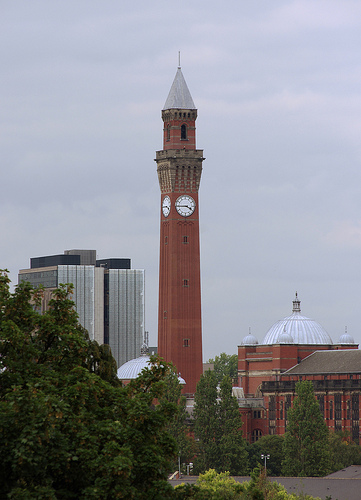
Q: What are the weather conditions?
A: It is cloudy.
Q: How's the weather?
A: It is cloudy.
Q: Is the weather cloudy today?
A: Yes, it is cloudy.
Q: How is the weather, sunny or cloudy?
A: It is cloudy.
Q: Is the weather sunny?
A: No, it is cloudy.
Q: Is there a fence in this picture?
A: No, there are no fences.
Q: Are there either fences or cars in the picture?
A: No, there are no fences or cars.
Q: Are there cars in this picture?
A: No, there are no cars.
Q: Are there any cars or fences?
A: No, there are no cars or fences.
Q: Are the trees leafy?
A: Yes, the trees are leafy.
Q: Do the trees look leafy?
A: Yes, the trees are leafy.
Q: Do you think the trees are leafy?
A: Yes, the trees are leafy.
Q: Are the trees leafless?
A: No, the trees are leafy.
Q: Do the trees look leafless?
A: No, the trees are leafy.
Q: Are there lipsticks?
A: No, there are no lipsticks.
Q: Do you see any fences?
A: No, there are no fences.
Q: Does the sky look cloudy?
A: Yes, the sky is cloudy.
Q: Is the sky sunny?
A: No, the sky is cloudy.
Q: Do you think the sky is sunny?
A: No, the sky is cloudy.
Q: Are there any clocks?
A: Yes, there is a clock.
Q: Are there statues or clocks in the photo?
A: Yes, there is a clock.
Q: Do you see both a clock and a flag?
A: No, there is a clock but no flags.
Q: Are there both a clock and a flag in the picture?
A: No, there is a clock but no flags.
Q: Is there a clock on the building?
A: Yes, there is a clock on the building.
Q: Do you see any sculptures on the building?
A: No, there is a clock on the building.